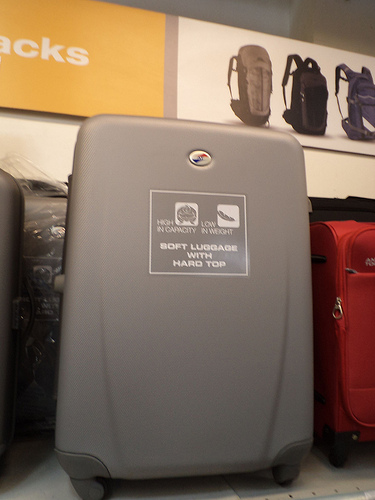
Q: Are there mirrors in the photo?
A: No, there are no mirrors.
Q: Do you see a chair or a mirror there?
A: No, there are no mirrors or chairs.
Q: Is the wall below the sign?
A: Yes, the wall is below the sign.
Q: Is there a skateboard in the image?
A: No, there are no skateboards.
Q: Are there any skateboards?
A: No, there are no skateboards.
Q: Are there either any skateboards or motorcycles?
A: No, there are no skateboards or motorcycles.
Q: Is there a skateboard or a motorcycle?
A: No, there are no skateboards or motorcycles.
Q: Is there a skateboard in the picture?
A: No, there are no skateboards.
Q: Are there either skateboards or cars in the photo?
A: No, there are no skateboards or cars.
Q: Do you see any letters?
A: Yes, there are letters.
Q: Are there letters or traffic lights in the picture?
A: Yes, there are letters.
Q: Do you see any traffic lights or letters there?
A: Yes, there are letters.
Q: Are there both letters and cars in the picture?
A: No, there are letters but no cars.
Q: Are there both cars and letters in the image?
A: No, there are letters but no cars.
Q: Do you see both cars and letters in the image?
A: No, there are letters but no cars.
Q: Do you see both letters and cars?
A: No, there are letters but no cars.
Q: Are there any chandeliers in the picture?
A: No, there are no chandeliers.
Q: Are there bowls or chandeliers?
A: No, there are no chandeliers or bowls.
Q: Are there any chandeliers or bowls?
A: No, there are no chandeliers or bowls.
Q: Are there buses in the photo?
A: No, there are no buses.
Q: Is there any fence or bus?
A: No, there are no buses or fences.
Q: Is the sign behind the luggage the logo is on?
A: Yes, the sign is behind the luggage.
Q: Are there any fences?
A: No, there are no fences.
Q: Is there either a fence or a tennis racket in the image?
A: No, there are no fences or rackets.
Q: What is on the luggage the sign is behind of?
A: The logo is on the luggage.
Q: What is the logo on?
A: The logo is on the luggage.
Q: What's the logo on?
A: The logo is on the luggage.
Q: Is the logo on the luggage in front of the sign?
A: Yes, the logo is on the luggage.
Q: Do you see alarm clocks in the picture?
A: No, there are no alarm clocks.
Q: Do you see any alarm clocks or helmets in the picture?
A: No, there are no alarm clocks or helmets.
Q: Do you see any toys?
A: No, there are no toys.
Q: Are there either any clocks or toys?
A: No, there are no toys or clocks.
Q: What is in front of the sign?
A: The luggage is in front of the sign.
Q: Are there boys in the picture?
A: No, there are no boys.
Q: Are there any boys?
A: No, there are no boys.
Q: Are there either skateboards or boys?
A: No, there are no boys or skateboards.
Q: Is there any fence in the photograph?
A: No, there are no fences.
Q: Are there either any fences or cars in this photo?
A: No, there are no fences or cars.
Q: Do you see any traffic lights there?
A: No, there are no traffic lights.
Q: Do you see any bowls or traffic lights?
A: No, there are no traffic lights or bowls.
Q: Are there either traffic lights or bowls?
A: No, there are no traffic lights or bowls.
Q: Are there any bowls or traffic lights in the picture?
A: No, there are no traffic lights or bowls.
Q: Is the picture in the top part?
A: Yes, the picture is in the top of the image.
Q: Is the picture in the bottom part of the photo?
A: No, the picture is in the top of the image.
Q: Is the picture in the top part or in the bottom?
A: The picture is in the top of the image.